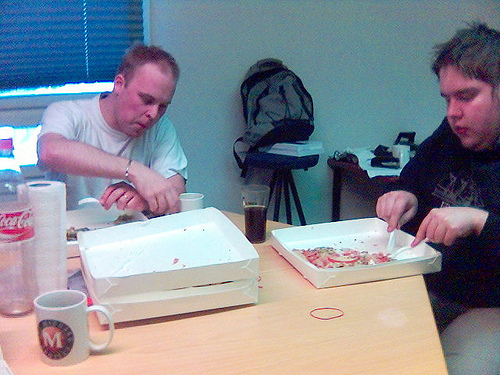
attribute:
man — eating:
[391, 24, 498, 344]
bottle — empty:
[0, 137, 35, 314]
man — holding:
[10, 24, 212, 295]